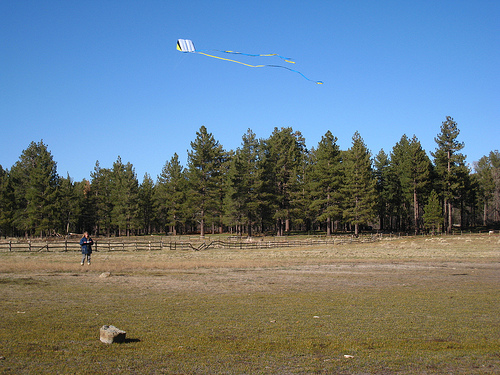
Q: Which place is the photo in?
A: It is at the field.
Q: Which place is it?
A: It is a field.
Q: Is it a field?
A: Yes, it is a field.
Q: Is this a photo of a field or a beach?
A: It is showing a field.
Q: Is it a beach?
A: No, it is a field.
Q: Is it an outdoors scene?
A: Yes, it is outdoors.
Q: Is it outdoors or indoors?
A: It is outdoors.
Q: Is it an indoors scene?
A: No, it is outdoors.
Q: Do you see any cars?
A: No, there are no cars.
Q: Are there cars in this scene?
A: No, there are no cars.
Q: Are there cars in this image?
A: No, there are no cars.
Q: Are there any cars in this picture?
A: No, there are no cars.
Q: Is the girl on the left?
A: Yes, the girl is on the left of the image.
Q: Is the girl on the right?
A: No, the girl is on the left of the image.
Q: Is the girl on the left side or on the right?
A: The girl is on the left of the image.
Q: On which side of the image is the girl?
A: The girl is on the left of the image.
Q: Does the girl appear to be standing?
A: Yes, the girl is standing.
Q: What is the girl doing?
A: The girl is standing.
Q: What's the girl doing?
A: The girl is standing.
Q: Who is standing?
A: The girl is standing.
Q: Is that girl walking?
A: No, the girl is standing.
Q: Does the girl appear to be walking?
A: No, the girl is standing.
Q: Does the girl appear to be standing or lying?
A: The girl is standing.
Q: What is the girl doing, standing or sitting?
A: The girl is standing.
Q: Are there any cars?
A: No, there are no cars.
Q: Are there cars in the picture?
A: No, there are no cars.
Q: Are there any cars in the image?
A: No, there are no cars.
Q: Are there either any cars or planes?
A: No, there are no cars or planes.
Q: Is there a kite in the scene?
A: Yes, there is a kite.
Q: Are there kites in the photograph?
A: Yes, there is a kite.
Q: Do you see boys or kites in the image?
A: Yes, there is a kite.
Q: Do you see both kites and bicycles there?
A: No, there is a kite but no bikes.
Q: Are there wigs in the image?
A: No, there are no wigs.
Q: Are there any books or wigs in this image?
A: No, there are no wigs or books.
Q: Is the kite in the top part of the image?
A: Yes, the kite is in the top of the image.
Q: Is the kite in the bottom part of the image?
A: No, the kite is in the top of the image.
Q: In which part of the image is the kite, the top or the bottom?
A: The kite is in the top of the image.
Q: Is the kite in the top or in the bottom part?
A: The kite is in the top of the image.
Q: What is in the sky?
A: The kite is in the sky.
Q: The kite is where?
A: The kite is in the sky.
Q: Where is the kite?
A: The kite is in the sky.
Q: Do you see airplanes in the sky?
A: No, there is a kite in the sky.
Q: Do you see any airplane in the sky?
A: No, there is a kite in the sky.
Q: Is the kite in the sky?
A: Yes, the kite is in the sky.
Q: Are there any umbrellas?
A: No, there are no umbrellas.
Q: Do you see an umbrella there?
A: No, there are no umbrellas.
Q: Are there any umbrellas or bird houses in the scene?
A: No, there are no umbrellas or bird houses.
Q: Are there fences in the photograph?
A: Yes, there is a fence.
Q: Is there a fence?
A: Yes, there is a fence.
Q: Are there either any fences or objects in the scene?
A: Yes, there is a fence.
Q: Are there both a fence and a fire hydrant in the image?
A: No, there is a fence but no fire hydrants.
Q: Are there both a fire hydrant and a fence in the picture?
A: No, there is a fence but no fire hydrants.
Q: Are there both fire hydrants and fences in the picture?
A: No, there is a fence but no fire hydrants.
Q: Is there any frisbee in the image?
A: No, there are no frisbees.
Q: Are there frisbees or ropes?
A: No, there are no frisbees or ropes.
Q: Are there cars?
A: No, there are no cars.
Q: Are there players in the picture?
A: No, there are no players.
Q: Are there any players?
A: No, there are no players.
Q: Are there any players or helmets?
A: No, there are no players or helmets.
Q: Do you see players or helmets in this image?
A: No, there are no players or helmets.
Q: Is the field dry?
A: Yes, the field is dry.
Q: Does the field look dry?
A: Yes, the field is dry.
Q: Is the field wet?
A: No, the field is dry.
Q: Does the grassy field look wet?
A: No, the field is dry.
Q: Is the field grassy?
A: Yes, the field is grassy.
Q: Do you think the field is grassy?
A: Yes, the field is grassy.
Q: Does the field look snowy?
A: No, the field is grassy.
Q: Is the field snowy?
A: No, the field is grassy.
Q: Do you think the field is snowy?
A: No, the field is grassy.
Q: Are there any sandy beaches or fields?
A: No, there is a field but it is grassy.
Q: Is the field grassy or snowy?
A: The field is grassy.